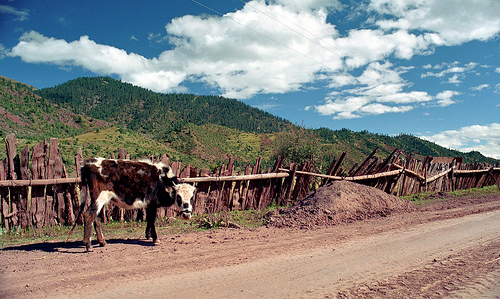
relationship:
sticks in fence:
[189, 155, 279, 201] [9, 152, 484, 224]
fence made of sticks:
[0, 126, 496, 227] [210, 157, 266, 204]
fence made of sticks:
[0, 126, 498, 227] [238, 159, 253, 208]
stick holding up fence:
[4, 129, 26, 231] [0, 126, 496, 227]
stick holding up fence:
[31, 138, 46, 226] [0, 126, 496, 227]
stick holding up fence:
[45, 132, 59, 224] [0, 126, 496, 227]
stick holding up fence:
[224, 149, 231, 213] [0, 126, 496, 227]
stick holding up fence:
[251, 155, 258, 212] [0, 126, 496, 227]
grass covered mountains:
[89, 94, 386, 194] [90, 64, 438, 211]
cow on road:
[61, 151, 247, 257] [70, 220, 494, 298]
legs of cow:
[78, 194, 108, 254] [65, 149, 206, 254]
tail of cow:
[70, 158, 91, 240] [65, 153, 200, 250]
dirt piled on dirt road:
[259, 183, 449, 264] [0, 195, 497, 299]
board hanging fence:
[0, 134, 500, 231] [0, 126, 496, 227]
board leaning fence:
[45, 132, 57, 183] [0, 126, 496, 227]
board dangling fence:
[0, 134, 500, 231] [0, 126, 496, 227]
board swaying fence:
[0, 134, 500, 231] [0, 126, 496, 227]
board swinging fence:
[0, 134, 500, 231] [0, 126, 496, 227]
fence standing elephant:
[0, 126, 498, 227] [4, 131, 498, 226]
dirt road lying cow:
[0, 195, 497, 299] [65, 153, 200, 250]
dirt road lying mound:
[0, 195, 497, 299] [262, 159, 416, 247]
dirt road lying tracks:
[13, 195, 498, 294] [352, 241, 484, 297]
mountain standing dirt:
[5, 76, 288, 145] [279, 185, 433, 262]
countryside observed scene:
[1, 0, 496, 295] [2, 3, 497, 297]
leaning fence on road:
[282, 142, 415, 206] [148, 218, 485, 295]